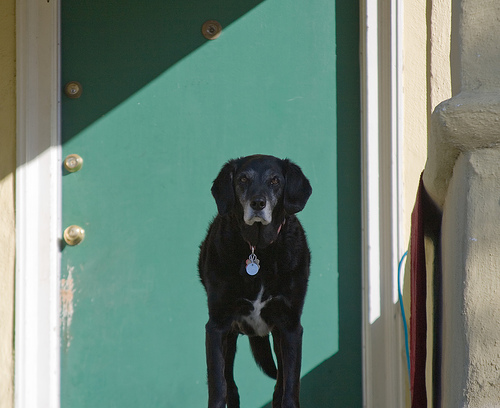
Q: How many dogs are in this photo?
A: One.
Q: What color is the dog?
A: Black.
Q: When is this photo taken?
A: Daytime.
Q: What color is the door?
A: Green.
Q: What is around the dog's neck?
A: A collar.